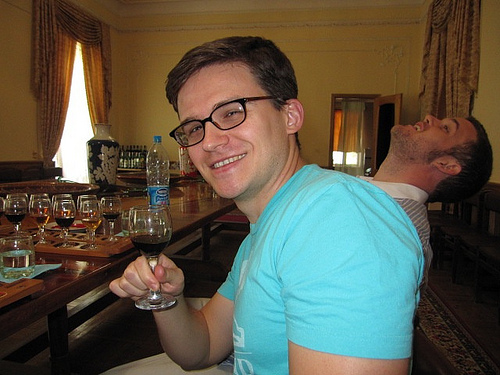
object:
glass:
[125, 203, 174, 310]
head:
[389, 112, 492, 197]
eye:
[221, 107, 246, 119]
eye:
[188, 125, 208, 133]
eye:
[441, 120, 451, 134]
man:
[108, 34, 427, 374]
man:
[360, 112, 493, 242]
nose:
[200, 121, 229, 153]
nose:
[422, 112, 439, 128]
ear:
[429, 153, 463, 175]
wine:
[129, 234, 172, 253]